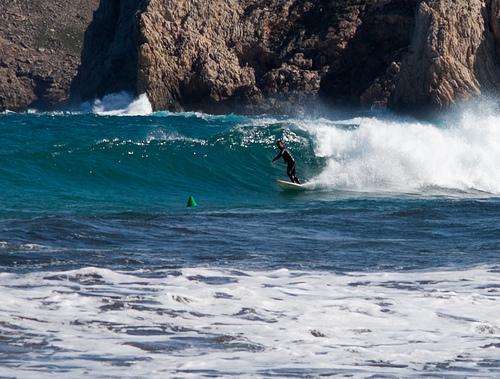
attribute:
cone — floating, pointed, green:
[181, 192, 201, 215]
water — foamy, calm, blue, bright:
[0, 96, 499, 378]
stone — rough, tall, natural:
[2, 0, 500, 117]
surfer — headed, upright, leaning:
[271, 139, 305, 189]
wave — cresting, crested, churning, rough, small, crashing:
[55, 122, 491, 192]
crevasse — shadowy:
[65, 5, 156, 107]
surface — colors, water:
[8, 172, 500, 311]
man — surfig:
[270, 135, 303, 188]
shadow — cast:
[64, 2, 157, 121]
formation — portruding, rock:
[1, 0, 499, 126]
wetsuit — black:
[276, 148, 305, 183]